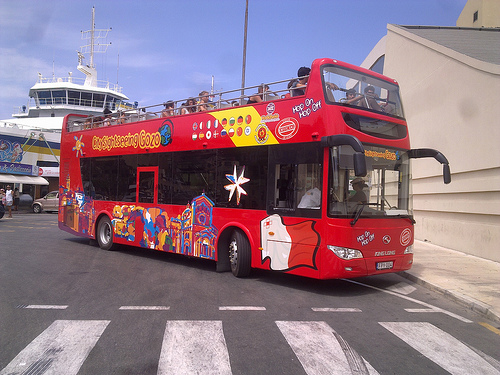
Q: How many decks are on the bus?
A: Two.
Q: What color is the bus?
A: Red.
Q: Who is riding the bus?
A: People.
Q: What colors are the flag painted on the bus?
A: Red & white.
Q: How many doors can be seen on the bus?
A: One.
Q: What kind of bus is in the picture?
A: Double decker.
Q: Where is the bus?
A: On the road.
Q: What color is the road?
A: Black.